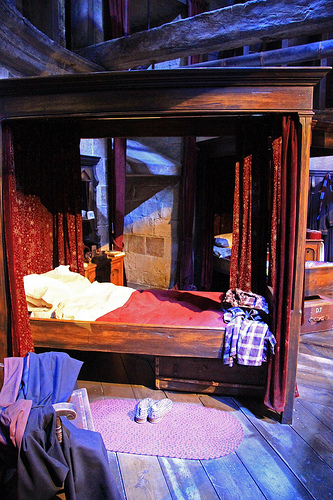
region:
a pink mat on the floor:
[175, 415, 240, 451]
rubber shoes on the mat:
[138, 406, 167, 418]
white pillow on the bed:
[29, 278, 85, 293]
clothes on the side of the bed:
[6, 366, 38, 432]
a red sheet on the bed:
[124, 305, 224, 326]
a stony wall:
[132, 233, 161, 280]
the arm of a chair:
[55, 403, 75, 421]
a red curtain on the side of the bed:
[16, 222, 74, 272]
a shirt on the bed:
[236, 317, 261, 362]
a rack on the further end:
[307, 270, 329, 324]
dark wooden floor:
[205, 409, 330, 497]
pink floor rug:
[87, 390, 246, 461]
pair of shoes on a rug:
[100, 393, 197, 436]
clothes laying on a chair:
[1, 350, 107, 490]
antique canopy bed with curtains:
[3, 76, 302, 407]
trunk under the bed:
[149, 352, 295, 400]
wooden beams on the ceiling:
[2, 1, 327, 65]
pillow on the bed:
[19, 256, 166, 327]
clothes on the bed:
[192, 286, 302, 409]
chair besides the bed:
[2, 78, 157, 489]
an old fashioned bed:
[3, 75, 305, 429]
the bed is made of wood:
[0, 94, 303, 415]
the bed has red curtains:
[4, 95, 306, 428]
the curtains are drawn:
[6, 109, 295, 430]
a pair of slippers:
[128, 388, 193, 437]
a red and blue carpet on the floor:
[90, 389, 252, 475]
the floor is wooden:
[85, 363, 329, 499]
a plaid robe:
[215, 272, 280, 380]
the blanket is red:
[75, 280, 253, 343]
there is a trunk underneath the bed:
[148, 352, 282, 410]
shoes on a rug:
[130, 393, 184, 440]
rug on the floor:
[109, 393, 253, 470]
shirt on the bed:
[226, 294, 268, 364]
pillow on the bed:
[21, 252, 95, 303]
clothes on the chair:
[6, 348, 99, 475]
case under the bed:
[150, 349, 276, 400]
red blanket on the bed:
[104, 274, 237, 332]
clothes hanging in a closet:
[315, 173, 332, 240]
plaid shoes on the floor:
[130, 388, 181, 427]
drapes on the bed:
[260, 100, 302, 346]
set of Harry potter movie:
[9, 8, 324, 490]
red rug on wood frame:
[74, 392, 244, 459]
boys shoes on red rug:
[131, 397, 175, 422]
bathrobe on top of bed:
[221, 286, 271, 367]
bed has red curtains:
[5, 116, 289, 416]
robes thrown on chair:
[0, 363, 122, 490]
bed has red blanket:
[31, 266, 235, 332]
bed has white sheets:
[26, 268, 228, 327]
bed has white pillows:
[28, 268, 90, 311]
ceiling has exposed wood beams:
[73, 0, 327, 68]